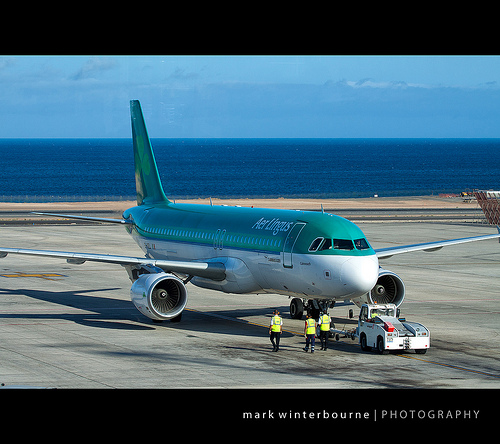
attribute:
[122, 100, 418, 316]
plane — green, parked, white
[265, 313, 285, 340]
man — walking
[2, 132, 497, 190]
water — blue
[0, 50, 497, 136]
sky — blue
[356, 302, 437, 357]
carrier — service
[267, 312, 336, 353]
people — walking